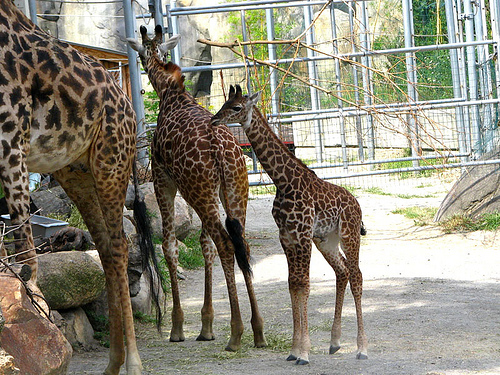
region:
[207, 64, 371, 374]
A young giraffe standing with other giraffes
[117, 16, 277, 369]
An older giraffe looking away from the camera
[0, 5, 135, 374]
The back half of a giraffe with its head out of view.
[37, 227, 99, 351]
A rock with some moss on its side.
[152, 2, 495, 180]
A fence part of the giraffe inclosure.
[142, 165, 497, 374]
Sandy ground part of the giraffe enclosure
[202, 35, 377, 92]
a large tree branch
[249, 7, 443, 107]
Some green vegetation outside of the giraffe enclosure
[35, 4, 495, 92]
A wall of rock outside the giraffe enclosure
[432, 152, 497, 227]
a large stone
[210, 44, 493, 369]
A young giraffe is at the zoo.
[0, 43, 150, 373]
Body of captive giraffe at zoo.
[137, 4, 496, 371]
Two young captive giraffes at zoo.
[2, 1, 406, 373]
A family of captive giraffes at zoo.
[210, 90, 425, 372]
Young giraffe looking at camera.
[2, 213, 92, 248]
Food or water tub for captive giraffes at zoo.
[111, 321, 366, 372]
Hooves of three different giraffes at zoo.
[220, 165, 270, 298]
Long giraffes tail with black hair at the tip.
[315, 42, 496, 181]
Part of the giraffe enclosure at the zoo.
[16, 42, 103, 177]
Belly area of adult giraffe at zoo.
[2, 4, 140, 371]
Giraffe standing on the rock.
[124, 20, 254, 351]
Adult giraffe.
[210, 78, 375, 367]
Baby giraffe.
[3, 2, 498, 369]
Giraffes are in an enclosed area.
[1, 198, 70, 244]
A blue tub is among the rocks.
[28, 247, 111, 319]
Moss growing on the rock.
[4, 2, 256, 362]
Adult giraffes have long tails.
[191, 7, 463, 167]
Branches hang on the fence.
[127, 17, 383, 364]
Baby giraffe stands to the left of the other giraffe.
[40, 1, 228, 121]
Large rock formation in the background.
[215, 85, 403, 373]
A juvenile giraffe.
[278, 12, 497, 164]
A metal barrier.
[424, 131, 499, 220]
A large stone.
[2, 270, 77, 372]
A red and brown rock.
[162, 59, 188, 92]
A tuft of brown hair on the giraffe's back.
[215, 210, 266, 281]
Black hair at the end of the tail.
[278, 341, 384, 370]
The giraffe has black hooves.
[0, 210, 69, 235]
A plastic bin.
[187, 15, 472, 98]
A large broken branch.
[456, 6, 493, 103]
Metal poles.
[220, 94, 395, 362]
the giraffe is brown and white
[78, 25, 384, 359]
The giraffes is in their cage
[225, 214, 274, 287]
The giraffe has a black tail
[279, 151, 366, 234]
The giraffe has brown spots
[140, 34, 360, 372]
The little giraffe is behind the big giraffe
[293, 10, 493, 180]
The gate is made of steel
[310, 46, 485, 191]
The gates are tall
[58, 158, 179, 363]
The giraffe has long legs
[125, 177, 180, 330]
The giraffe tail is long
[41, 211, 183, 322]
The rocks are next to the giraffe.